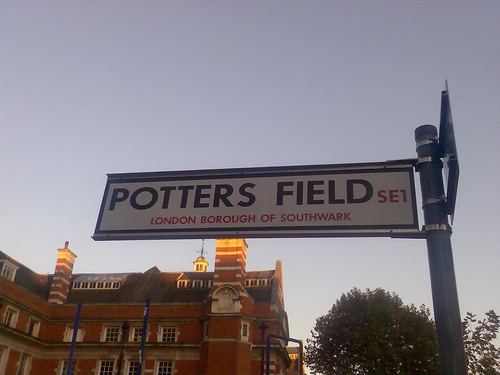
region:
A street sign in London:
[65, 120, 475, 266]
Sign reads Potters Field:
[77, 131, 457, 251]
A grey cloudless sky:
[22, 92, 389, 142]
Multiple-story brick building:
[72, 271, 300, 372]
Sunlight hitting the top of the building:
[46, 221, 267, 264]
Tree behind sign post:
[323, 276, 441, 371]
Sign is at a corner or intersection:
[368, 108, 474, 368]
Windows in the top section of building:
[73, 276, 275, 289]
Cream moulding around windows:
[150, 318, 185, 343]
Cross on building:
[249, 311, 281, 349]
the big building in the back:
[0, 208, 313, 369]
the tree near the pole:
[312, 278, 499, 371]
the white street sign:
[92, 156, 422, 244]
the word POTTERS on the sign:
[110, 184, 255, 211]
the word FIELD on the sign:
[272, 175, 374, 207]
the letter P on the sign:
[106, 185, 127, 214]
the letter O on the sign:
[127, 182, 159, 209]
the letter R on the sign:
[212, 182, 234, 209]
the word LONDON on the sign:
[144, 212, 198, 227]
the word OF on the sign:
[256, 210, 277, 222]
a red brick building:
[0, 249, 305, 374]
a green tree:
[293, 270, 493, 373]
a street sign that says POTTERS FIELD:
[87, 156, 429, 246]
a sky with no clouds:
[2, 3, 499, 277]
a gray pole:
[410, 103, 476, 373]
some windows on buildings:
[85, 306, 195, 373]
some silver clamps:
[410, 126, 459, 243]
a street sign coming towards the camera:
[431, 77, 470, 237]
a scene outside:
[0, 0, 491, 373]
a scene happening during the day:
[5, 4, 497, 373]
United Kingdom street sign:
[80, 73, 477, 250]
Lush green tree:
[301, 275, 429, 373]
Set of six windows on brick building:
[92, 308, 188, 373]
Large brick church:
[0, 237, 305, 373]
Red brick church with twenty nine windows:
[0, 238, 302, 373]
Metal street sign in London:
[67, 93, 483, 253]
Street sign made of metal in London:
[81, 89, 499, 255]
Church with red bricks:
[0, 239, 305, 374]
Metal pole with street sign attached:
[411, 76, 476, 371]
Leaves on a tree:
[303, 286, 428, 373]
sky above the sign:
[185, 26, 290, 93]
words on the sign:
[70, 175, 400, 246]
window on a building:
[100, 312, 187, 347]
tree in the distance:
[331, 270, 396, 347]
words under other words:
[140, 207, 360, 233]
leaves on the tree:
[335, 306, 380, 336]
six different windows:
[105, 321, 185, 361]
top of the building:
[56, 230, 77, 265]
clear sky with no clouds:
[63, 80, 233, 146]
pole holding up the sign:
[417, 78, 485, 352]